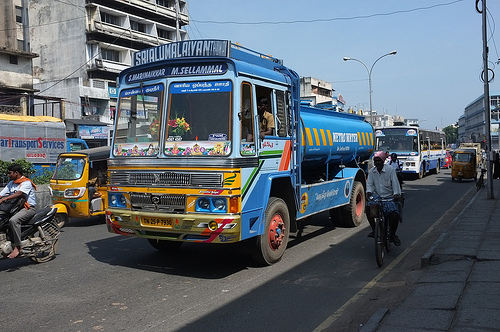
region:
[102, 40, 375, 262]
blue and yellow tanker truck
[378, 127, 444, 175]
blue and white bus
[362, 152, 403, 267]
person in white shirt and shorts on a bicycle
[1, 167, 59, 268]
person with orange scarf on a motorcycle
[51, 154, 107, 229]
small yellow cab behind the motorcycle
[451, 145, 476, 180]
yellow cab on curb by the bus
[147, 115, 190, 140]
flowers in the windshield of tanker truck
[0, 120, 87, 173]
gray and blue Transport Services truck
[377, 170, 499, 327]
brick sidewalk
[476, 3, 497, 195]
tall pole on the sidewalk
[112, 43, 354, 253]
a blue decorated truck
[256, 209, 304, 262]
the rims are red in colour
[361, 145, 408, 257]
a man riding a bicycle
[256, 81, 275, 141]
a man with his hand out the window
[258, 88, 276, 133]
the window is open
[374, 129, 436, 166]
a white and blue bus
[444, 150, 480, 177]
a parked yellow tuktuk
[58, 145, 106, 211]
a shiny yellow tuktuk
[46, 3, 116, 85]
a tal;l old white building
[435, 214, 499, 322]
a square tilled pavement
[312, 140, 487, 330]
person riding bicycle on road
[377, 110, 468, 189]
blue and white bus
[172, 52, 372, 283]
person driving blue truck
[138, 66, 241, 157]
bunch of flowers in windshield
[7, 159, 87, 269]
man riding motorbike barefoot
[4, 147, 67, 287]
man wearing orange scarf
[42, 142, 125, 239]
three-wheel yellow vehicle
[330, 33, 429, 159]
streetlights over the street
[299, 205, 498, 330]
break in curb for driveway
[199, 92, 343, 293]
red rims on truck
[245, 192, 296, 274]
The front left wheel of a truck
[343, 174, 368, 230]
The rear left wheel of a truck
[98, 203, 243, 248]
The front bumper of a truck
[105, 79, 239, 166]
The front window of a truck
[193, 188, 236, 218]
The front left headlights of a truck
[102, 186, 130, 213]
The front right headlights of a truck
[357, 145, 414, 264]
A man riding a bike on a street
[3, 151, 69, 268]
A man riding a motorcycle on a street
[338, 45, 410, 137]
Two street lights on a pole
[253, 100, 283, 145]
A man in a truck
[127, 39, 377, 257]
the lorri is blue and yellow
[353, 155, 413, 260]
the person is on the bike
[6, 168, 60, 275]
man is on the bike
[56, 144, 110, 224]
the car is yellow and grey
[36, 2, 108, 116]
the building is made of concrete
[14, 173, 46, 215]
the scarf is orange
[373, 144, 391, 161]
the traaban is orange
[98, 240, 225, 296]
shadow is on the ground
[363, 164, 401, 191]
his shirt is white